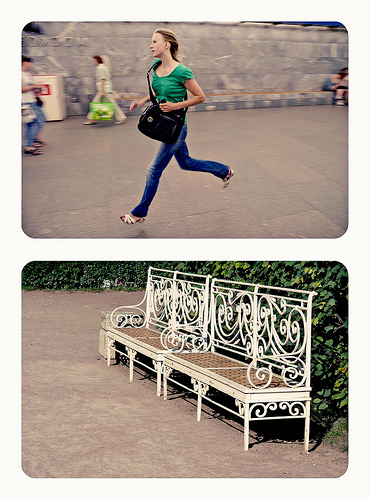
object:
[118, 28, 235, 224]
woman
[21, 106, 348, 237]
street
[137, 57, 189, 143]
purse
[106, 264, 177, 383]
benches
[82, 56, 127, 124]
woman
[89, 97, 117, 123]
bag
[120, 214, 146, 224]
sandals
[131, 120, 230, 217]
jeans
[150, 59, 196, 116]
shirt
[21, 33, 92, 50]
logo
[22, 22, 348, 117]
wall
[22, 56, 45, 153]
person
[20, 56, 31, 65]
cap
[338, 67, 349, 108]
people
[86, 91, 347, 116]
bench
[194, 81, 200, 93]
skin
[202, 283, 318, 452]
bench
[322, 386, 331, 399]
leaves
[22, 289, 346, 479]
pavement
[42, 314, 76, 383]
part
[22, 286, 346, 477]
floor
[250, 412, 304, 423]
part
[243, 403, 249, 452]
stand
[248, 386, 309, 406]
edge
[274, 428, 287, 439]
part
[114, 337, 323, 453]
shade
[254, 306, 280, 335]
part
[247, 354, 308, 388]
metal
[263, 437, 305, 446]
edge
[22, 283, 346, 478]
ground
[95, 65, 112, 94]
shirt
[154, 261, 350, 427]
bushes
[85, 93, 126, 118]
pants